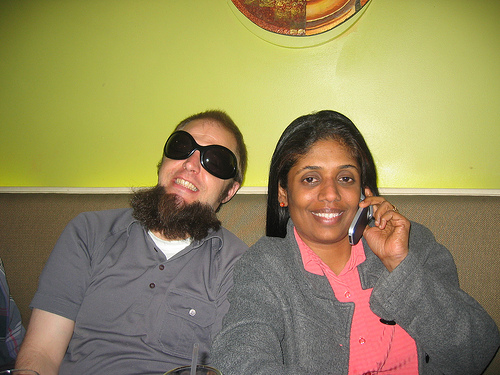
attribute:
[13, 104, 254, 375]
man — smiling, seated, grinning, sitting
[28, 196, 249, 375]
shirt — gray, pink, grey, short sleeved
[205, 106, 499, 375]
woman — sitting, seated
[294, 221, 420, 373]
shirt — pink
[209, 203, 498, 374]
jacket — grey, gray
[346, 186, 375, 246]
cell phone — silver, mobile, gray, black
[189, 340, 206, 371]
straw — plastic, clear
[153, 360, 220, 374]
cup — plastic, cylindrical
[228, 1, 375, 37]
art — brown orange yellow, circular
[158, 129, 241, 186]
sunglasses — black, large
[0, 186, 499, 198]
strip — wooden, white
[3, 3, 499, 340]
wall — green, brown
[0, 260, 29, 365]
shirt — blue white, plaid, red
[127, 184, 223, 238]
beard — long, brown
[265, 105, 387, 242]
hair — black, long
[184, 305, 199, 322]
button — white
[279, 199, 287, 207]
earring — red, round